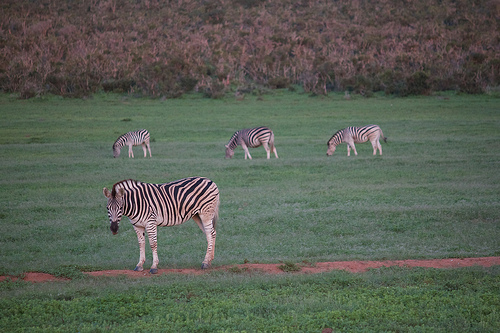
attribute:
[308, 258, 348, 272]
trail — bushes